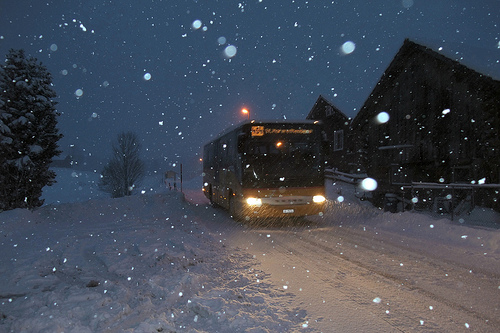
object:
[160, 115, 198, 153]
snowflake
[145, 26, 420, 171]
snow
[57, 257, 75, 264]
snow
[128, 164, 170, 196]
snow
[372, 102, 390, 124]
snow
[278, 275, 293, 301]
snow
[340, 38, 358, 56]
snow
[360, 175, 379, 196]
snow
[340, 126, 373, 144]
snow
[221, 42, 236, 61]
snow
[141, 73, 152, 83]
snow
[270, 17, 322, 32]
snow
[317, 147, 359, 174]
snowflake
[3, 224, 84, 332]
snow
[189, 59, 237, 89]
snowflake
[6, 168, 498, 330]
snow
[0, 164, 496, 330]
ground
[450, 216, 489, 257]
snowflake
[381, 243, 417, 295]
speck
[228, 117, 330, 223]
bus front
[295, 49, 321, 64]
snow speck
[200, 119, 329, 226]
bus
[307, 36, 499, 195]
house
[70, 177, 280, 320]
roadside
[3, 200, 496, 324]
snow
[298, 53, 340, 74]
snow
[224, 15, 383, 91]
sky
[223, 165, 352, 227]
headlights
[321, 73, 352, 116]
snowflake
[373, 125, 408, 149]
snowflake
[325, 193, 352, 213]
snowflake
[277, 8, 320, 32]
snowflake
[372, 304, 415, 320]
snowflake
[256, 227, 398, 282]
snow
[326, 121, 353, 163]
window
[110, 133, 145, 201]
leafless tree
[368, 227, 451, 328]
road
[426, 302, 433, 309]
speck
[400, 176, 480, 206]
snow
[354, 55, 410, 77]
snow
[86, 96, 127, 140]
snow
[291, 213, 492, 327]
tracks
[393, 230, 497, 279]
snow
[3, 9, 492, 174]
ground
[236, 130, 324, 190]
windshield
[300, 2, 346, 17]
snow speck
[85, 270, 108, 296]
dog poop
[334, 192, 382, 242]
snow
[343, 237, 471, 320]
snow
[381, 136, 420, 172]
speck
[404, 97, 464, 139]
snow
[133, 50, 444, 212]
snow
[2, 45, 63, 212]
tree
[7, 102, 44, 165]
snow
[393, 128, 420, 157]
snow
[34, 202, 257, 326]
snowbank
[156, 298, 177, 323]
snow speck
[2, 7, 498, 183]
air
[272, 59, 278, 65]
snow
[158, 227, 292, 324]
footprints